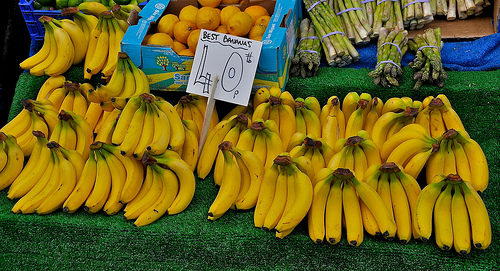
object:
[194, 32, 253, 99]
number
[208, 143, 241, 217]
banana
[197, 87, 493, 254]
bananas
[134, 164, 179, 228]
banana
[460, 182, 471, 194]
green stem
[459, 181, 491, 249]
banana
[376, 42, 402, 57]
rubber bands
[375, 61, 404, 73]
rubber bands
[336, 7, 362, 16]
rubber bands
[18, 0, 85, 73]
box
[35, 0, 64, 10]
limes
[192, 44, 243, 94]
price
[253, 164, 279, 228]
banana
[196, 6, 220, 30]
fruit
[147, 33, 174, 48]
fruit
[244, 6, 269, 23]
fruit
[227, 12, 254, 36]
fruit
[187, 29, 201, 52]
fruit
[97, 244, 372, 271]
grass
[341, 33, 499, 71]
tarp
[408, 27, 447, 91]
asparagus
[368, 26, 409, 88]
asparagus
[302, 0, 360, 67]
asparagus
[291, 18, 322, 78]
asparagus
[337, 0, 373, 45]
asparagus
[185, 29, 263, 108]
sign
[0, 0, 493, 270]
stand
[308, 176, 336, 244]
banana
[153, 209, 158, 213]
spot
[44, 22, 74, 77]
banana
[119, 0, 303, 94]
box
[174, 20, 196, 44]
orange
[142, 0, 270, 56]
oranges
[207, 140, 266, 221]
banana bundle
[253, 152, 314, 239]
banana bundle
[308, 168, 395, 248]
banana bundle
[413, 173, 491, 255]
banana bundle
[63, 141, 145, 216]
banana bundle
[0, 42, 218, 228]
bananas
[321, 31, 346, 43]
bands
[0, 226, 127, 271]
fuzzy material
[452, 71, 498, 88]
table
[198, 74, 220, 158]
stick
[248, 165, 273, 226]
banana